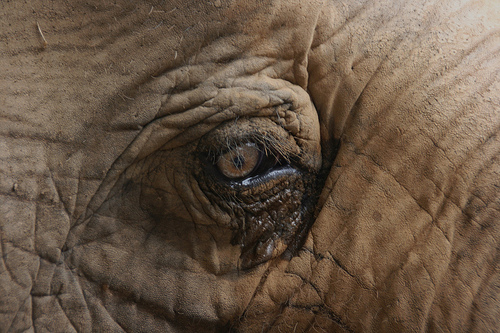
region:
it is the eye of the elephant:
[203, 123, 300, 218]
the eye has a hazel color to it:
[219, 141, 267, 178]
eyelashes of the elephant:
[218, 125, 275, 153]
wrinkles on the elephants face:
[176, 43, 298, 112]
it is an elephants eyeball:
[178, 80, 342, 275]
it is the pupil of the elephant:
[231, 156, 246, 168]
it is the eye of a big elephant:
[12, 6, 492, 325]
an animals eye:
[153, 79, 362, 264]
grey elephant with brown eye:
[126, 38, 413, 288]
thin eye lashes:
[205, 120, 283, 153]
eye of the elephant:
[211, 136, 311, 203]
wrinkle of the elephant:
[376, 170, 410, 205]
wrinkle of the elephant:
[314, 253, 358, 290]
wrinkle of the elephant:
[126, 286, 172, 311]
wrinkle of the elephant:
[433, 230, 468, 260]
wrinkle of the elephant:
[69, 167, 99, 194]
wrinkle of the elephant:
[152, 103, 194, 140]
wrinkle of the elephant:
[282, 56, 332, 95]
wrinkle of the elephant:
[151, 54, 193, 83]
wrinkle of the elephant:
[131, 293, 176, 328]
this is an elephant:
[23, 19, 455, 293]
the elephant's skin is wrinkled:
[42, 149, 124, 270]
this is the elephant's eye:
[129, 130, 325, 244]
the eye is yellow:
[208, 130, 288, 201]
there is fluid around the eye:
[230, 185, 389, 285]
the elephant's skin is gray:
[84, 58, 467, 308]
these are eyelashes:
[196, 131, 296, 175]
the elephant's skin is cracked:
[17, 191, 421, 313]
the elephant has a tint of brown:
[340, 63, 496, 246]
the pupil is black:
[222, 151, 253, 171]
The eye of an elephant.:
[1, 0, 498, 332]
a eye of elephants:
[215, 131, 265, 193]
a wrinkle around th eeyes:
[90, 81, 345, 233]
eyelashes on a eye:
[224, 141, 281, 163]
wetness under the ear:
[210, 170, 312, 270]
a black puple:
[234, 153, 246, 170]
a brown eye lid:
[212, 120, 300, 163]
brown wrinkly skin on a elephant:
[0, 6, 137, 159]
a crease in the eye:
[297, 121, 382, 261]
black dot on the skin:
[396, 6, 492, 168]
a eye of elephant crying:
[37, 26, 472, 302]